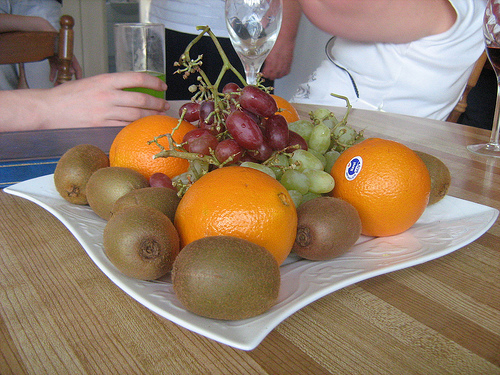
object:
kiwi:
[287, 194, 361, 260]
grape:
[234, 85, 277, 116]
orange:
[324, 137, 428, 237]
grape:
[223, 110, 263, 149]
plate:
[1, 171, 498, 355]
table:
[0, 100, 500, 375]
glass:
[224, 0, 283, 85]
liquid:
[120, 72, 167, 99]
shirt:
[288, 0, 488, 123]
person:
[285, 0, 492, 122]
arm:
[0, 89, 52, 132]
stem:
[149, 151, 218, 164]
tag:
[344, 155, 364, 181]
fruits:
[173, 235, 281, 320]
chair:
[0, 13, 83, 90]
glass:
[114, 23, 166, 101]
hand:
[48, 69, 171, 129]